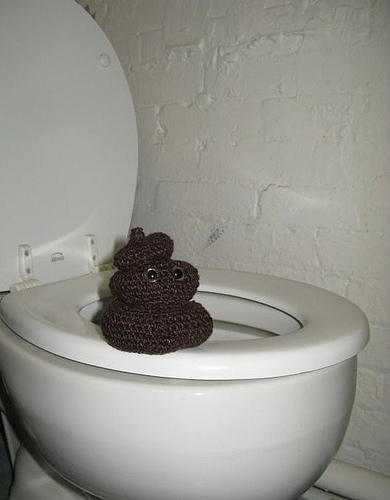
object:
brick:
[74, 0, 390, 482]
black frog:
[101, 227, 213, 356]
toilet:
[0, 0, 390, 500]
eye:
[172, 267, 184, 280]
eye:
[147, 268, 158, 280]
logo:
[51, 252, 65, 263]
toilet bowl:
[0, 0, 370, 500]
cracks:
[129, 1, 377, 231]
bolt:
[100, 54, 110, 67]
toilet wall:
[80, 0, 390, 500]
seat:
[0, 266, 370, 379]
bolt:
[91, 238, 97, 261]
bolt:
[25, 250, 29, 256]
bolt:
[26, 268, 30, 274]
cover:
[0, 0, 138, 290]